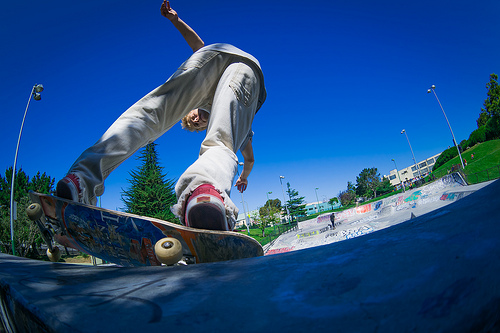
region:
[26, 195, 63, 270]
Front skateboard wheel axle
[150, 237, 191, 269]
Back skateboard left wheel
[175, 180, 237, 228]
Man's right red shoe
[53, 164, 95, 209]
Man's left red shoe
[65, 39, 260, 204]
Light beige skater jeans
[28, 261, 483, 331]
Large gray concrete wall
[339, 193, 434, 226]
Painting on the concrete walls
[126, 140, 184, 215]
Large green pine tree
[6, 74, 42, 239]
Tall silver light pole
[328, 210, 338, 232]
Second skater standing in the background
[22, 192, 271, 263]
A skateboard in the skate park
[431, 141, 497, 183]
A grassy field near the lamp posts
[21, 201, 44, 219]
A wheel on the skateboard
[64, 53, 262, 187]
The skater is wearing pants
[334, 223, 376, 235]
Graffiti on the ground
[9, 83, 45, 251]
A lamp post near the skater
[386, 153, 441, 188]
A building by the trees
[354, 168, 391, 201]
A tree beyond the skate park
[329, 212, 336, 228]
Another person in the skate park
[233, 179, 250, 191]
The right hand of the skater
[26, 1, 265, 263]
Man is skate boarding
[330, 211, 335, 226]
Someone is standing around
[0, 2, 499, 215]
Sky is clear and blue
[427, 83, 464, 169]
A tall metal light pole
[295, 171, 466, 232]
Concrete skate board ramp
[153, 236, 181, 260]
The wheel is yellow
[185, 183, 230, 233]
Shoe is red and white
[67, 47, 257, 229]
The pants are white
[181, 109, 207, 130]
The guy is looking down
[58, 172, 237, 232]
man's red and white shoes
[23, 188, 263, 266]
skateboard on a ramp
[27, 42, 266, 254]
man on a skateboard looking back toward the camera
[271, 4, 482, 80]
bright blue skies atove the skateboard park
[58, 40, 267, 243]
man on a skateboard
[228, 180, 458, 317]
outdoor skateboard ramp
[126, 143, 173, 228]
tall green tree behind the skateboarder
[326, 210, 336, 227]
person wearing dark clothing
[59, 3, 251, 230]
man on a skateboard ramp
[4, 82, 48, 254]
light pole near the skate park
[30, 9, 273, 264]
the person is skateboarding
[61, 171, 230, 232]
the person is wearing sneakers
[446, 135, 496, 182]
the hills are green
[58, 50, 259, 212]
the man is wearing long pants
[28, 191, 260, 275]
the skateboard has wheels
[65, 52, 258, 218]
the man has beige pants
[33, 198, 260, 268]
the board has designs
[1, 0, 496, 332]
the scene takes place coutdoors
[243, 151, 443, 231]
the buildings are in the distance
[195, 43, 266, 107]
the man has a gray shirt